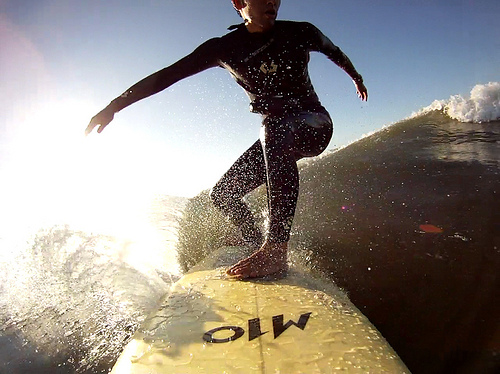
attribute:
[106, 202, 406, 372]
surfboard — white, long, wet, light, large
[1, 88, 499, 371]
water — splashing, grey, dark, dirty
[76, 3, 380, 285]
man — surfing, leaning, riding, standing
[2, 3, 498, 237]
sky — clear, sunny, blue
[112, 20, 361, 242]
wet suit — black, dark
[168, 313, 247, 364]
letter — o, black